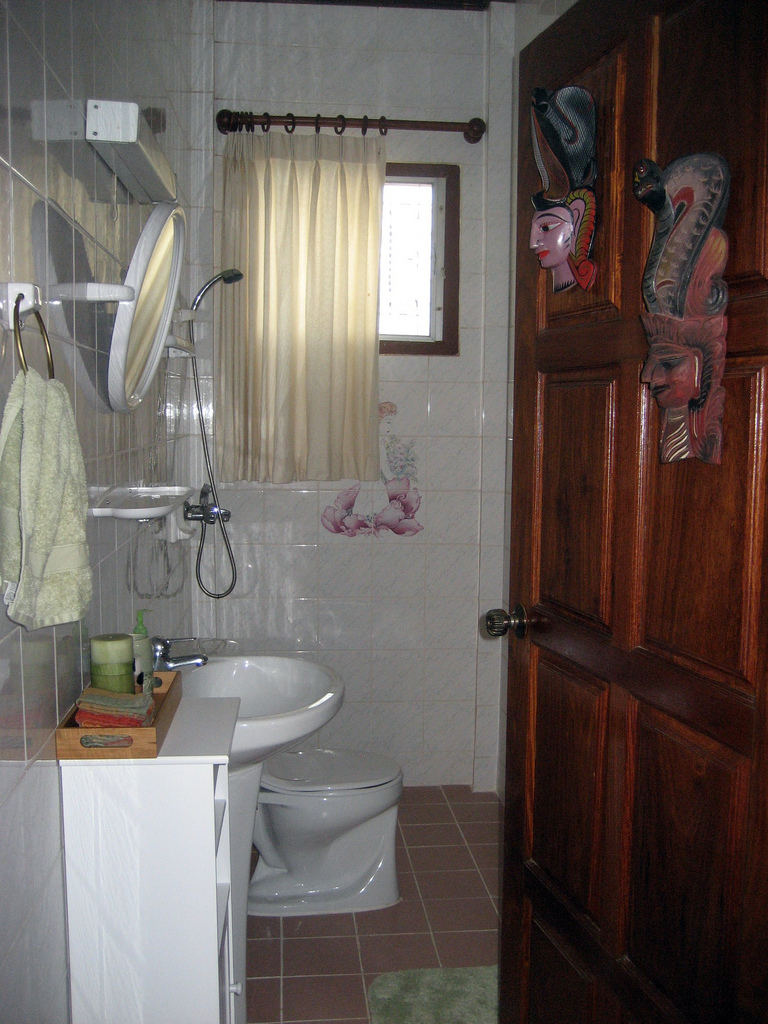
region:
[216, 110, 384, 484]
the curtain is hanging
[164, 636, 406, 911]
the toilet is white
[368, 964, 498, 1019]
the rug is light green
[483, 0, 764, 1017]
the masks hanging on the door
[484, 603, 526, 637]
the doorknob is dark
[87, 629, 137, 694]
the candle is green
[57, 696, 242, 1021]
the shelf is white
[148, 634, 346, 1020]
the pedestal sink is white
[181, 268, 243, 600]
the shower head at the end of the hose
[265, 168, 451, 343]
The window in the bathroom on the tile wall.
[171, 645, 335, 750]
The basin of the sink next to the shower.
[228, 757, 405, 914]
The toilet next to the sink in the bathroom.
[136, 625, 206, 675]
The silver faucet and knob of the sink.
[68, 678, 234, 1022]
The white wooden cabinet next to the sink.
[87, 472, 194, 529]
The white soap dishes mounted on the wall.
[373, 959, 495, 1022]
The rug on the floor next to the door.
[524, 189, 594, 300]
The Egyptian mask mounted on the wooden door.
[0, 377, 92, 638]
The towel hanging from the gold circle on the wall.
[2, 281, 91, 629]
White fluffy towel hanging on a gold towel ring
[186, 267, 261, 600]
Silver hand held shower head with a long silver hose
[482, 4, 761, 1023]
Cherry wood door with several panels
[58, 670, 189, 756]
A wood tray with cutout handles on each end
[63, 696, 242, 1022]
White stand with two shelves and a door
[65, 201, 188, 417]
White adjustable wall mirror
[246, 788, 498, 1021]
Brown tile floor with part of a light green bathroom rug visible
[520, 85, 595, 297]
Egyptian wall hanging of a head with a snake crown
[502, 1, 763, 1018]
Dark wood door with some Egyptian artwork on it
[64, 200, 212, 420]
a round mirror on a hinge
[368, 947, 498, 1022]
a pale green bath mat on floor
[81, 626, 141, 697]
a two tone green pillar candle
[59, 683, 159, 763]
a stack of colorful wash clothes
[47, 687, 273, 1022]
a simple white piece of furniture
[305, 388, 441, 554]
a decorative piece on the tile wall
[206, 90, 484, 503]
a short white curtain hanging off a rod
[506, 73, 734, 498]
a pair of exotic objects on door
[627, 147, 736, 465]
red and black door art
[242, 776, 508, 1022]
blush colored floor with green rug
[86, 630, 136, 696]
white and green candle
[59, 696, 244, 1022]
painted white wood storage unit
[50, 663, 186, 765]
wood tray with washcloths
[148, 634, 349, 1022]
silver faucet and white sink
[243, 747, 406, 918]
short clean shiny white toilet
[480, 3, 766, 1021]
dark brown bathroom door with dark knob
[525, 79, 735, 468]
two pieces of cultural artwork on a door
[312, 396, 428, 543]
flower decal on bathroom wall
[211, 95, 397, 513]
shower curtains on a rod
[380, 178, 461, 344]
A window on a building.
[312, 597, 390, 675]
A tile in a wall.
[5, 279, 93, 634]
a towel on a ring holder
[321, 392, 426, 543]
white tiles painted with flowers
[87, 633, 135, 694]
a green wax candle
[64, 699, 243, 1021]
a white shelving unit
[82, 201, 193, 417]
a white oval mirror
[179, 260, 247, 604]
a silver hand held shower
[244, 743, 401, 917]
a white ceramic toilet bowl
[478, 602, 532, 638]
a round brass door handle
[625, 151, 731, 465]
an ornate male mask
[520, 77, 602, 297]
an ornate female mask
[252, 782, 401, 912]
a white porcelain toilet bowl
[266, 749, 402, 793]
a white toilet seat lid